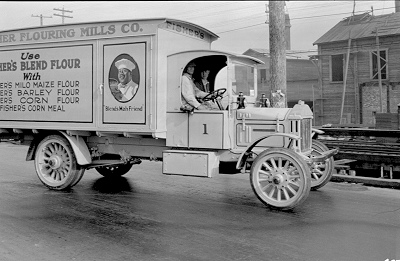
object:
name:
[163, 20, 206, 39]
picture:
[107, 51, 141, 103]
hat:
[183, 60, 198, 69]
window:
[329, 52, 342, 82]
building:
[313, 0, 398, 184]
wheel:
[223, 142, 317, 214]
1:
[201, 121, 209, 134]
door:
[186, 111, 223, 149]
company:
[0, 18, 144, 46]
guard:
[231, 151, 258, 175]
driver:
[179, 64, 224, 109]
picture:
[0, 0, 398, 261]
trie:
[248, 145, 311, 213]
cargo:
[1, 22, 170, 124]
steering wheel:
[200, 87, 226, 99]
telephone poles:
[52, 7, 75, 24]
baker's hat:
[114, 57, 136, 72]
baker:
[107, 58, 138, 102]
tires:
[28, 134, 90, 190]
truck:
[1, 16, 335, 210]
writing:
[73, 58, 81, 69]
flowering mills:
[19, 19, 119, 47]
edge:
[234, 147, 247, 170]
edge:
[295, 161, 314, 198]